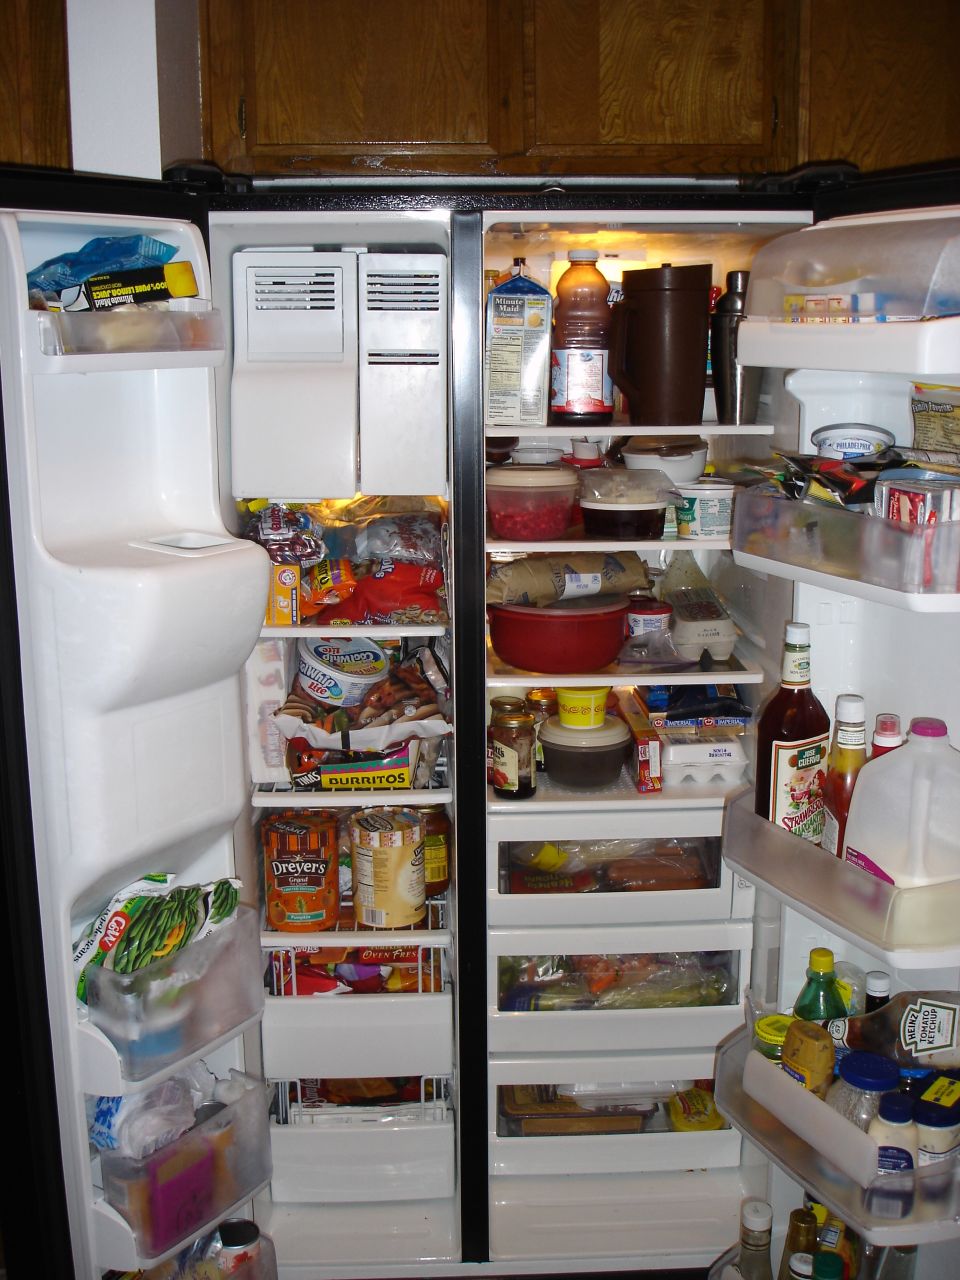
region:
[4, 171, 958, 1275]
an open refrigerator freezer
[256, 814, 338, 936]
a carton of ice cream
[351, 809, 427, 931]
a carton of ice cream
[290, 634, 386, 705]
a frozen carton of whipped topping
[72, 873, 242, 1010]
a bag of frozen green beans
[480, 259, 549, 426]
a carton of orange juice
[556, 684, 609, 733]
a yellow tub of butter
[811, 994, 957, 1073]
a near empty bottle of ketchup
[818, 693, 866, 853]
a bottle of ketchup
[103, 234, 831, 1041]
items in the fridge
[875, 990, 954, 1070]
words on the bottle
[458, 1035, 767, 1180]
bottom droor in the fridge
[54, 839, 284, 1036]
bag of green food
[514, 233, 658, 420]
drink in the fridge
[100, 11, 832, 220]
cabinets above the fridge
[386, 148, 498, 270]
light hitting the fridge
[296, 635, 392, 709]
white tub of Cool Whip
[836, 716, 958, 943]
plastic gallon jug of milk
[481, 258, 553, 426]
carton of Minute Maid orange juice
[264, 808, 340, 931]
orange carton of Dreyer's ice cream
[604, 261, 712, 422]
brown plastic Tupperware pitcher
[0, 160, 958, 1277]
very full refrigerator freezer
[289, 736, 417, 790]
individual package of a frozen burrito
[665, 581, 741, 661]
cardboard carton of a dozen eggs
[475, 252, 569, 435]
carton of minute maid juice on shelf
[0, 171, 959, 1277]
refrigerator with doors opened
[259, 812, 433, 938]
dreyers ice cream on shelf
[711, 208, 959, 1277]
door has 5 shelves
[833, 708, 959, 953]
gallon of milk on door shelf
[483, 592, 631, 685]
red bowl on shelf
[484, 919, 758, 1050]
vegetables inside the drawer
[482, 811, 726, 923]
hot dogs inside drawer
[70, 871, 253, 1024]
bag of frozen vegetables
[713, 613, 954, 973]
milk in refrigerator shelve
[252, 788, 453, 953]
ice cream in freezer shelve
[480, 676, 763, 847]
eggs in refrigerator shelve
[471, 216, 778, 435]
juice in fridge shelve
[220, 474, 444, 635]
chocolate in freezer shelve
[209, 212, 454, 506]
ice compartment in freezer shelve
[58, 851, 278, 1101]
green beans in freezer door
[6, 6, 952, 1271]
cabinet on top of refrigerator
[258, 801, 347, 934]
A ice cream carton sits on a shelf.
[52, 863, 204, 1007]
A bag of green beans on the door.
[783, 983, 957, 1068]
A bottle of ketchup turned on it's side.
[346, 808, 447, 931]
A carton of ice cream sits on a shelf.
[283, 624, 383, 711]
A tub of whip cream on the shelf.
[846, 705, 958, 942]
A gallon of milk half full.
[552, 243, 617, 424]
A bottle of juice sits on a shelf.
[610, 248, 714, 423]
A pitcher of juice sits on the shelf.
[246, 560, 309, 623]
A yellow box of baking soda sits on the shelf.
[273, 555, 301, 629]
The baking soda in the fridge.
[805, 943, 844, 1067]
The bottle of lemon juice.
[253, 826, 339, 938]
The container of Dryers icecream.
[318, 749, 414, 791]
The pack of burritos in the freezer.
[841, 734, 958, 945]
The gallon of milk in the fridge.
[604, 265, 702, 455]
The brown pitcher in the fridge.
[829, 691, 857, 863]
The ketchup bottle in the fridge.